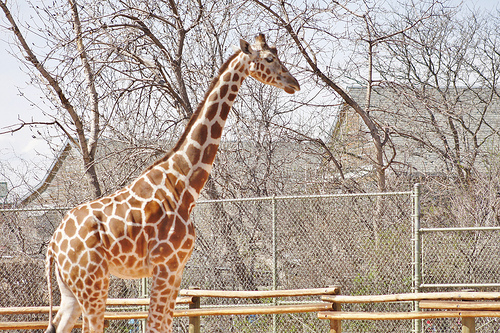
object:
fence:
[1, 183, 499, 333]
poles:
[411, 182, 422, 332]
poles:
[269, 194, 279, 332]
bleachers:
[0, 289, 497, 332]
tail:
[48, 248, 58, 332]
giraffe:
[37, 34, 300, 332]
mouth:
[282, 81, 302, 95]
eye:
[264, 55, 275, 64]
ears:
[238, 38, 254, 59]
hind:
[49, 208, 92, 298]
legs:
[148, 266, 171, 332]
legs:
[163, 272, 180, 332]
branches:
[370, 6, 437, 45]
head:
[238, 35, 302, 96]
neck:
[172, 69, 253, 195]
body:
[46, 172, 197, 282]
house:
[315, 84, 500, 228]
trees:
[253, 1, 412, 250]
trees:
[351, 0, 498, 226]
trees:
[0, 1, 111, 200]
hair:
[139, 52, 246, 173]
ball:
[42, 323, 56, 333]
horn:
[256, 31, 270, 47]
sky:
[1, 0, 499, 206]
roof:
[345, 87, 500, 174]